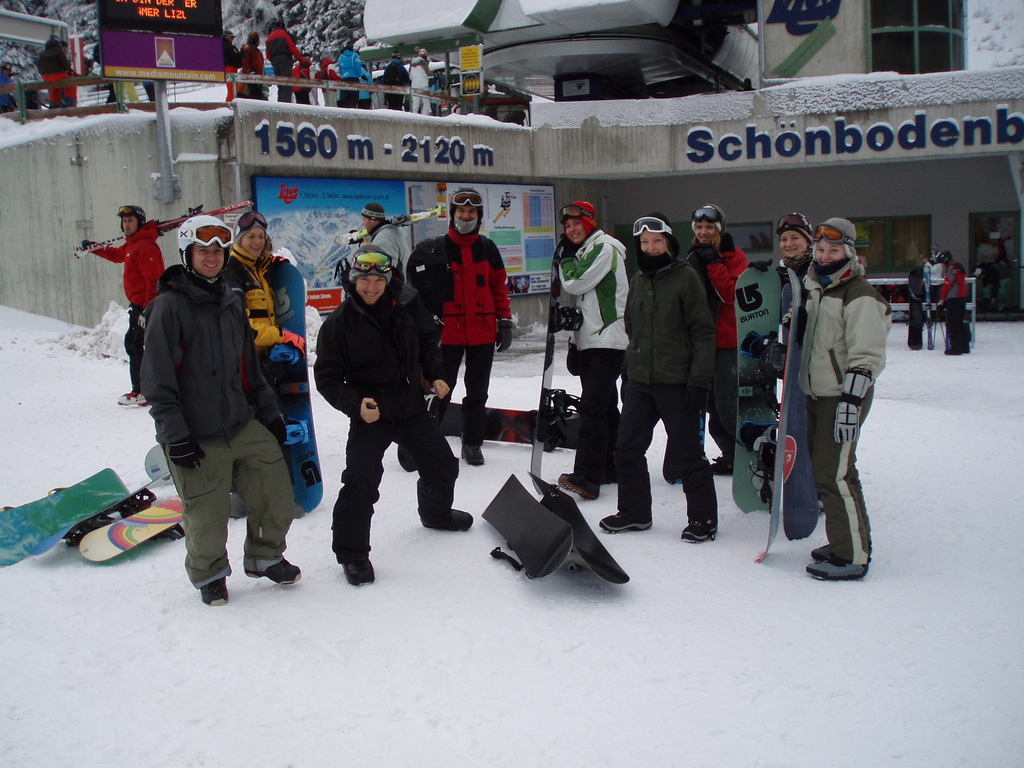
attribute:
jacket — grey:
[138, 273, 284, 447]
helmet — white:
[157, 212, 260, 288]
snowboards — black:
[483, 475, 624, 589]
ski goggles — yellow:
[337, 250, 404, 285]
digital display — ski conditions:
[88, 4, 250, 96]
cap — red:
[549, 196, 601, 232]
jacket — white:
[549, 240, 632, 359]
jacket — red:
[106, 235, 163, 308]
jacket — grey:
[603, 260, 728, 391]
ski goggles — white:
[603, 207, 687, 243]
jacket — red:
[88, 197, 181, 359]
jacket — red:
[88, 203, 175, 339]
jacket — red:
[92, 200, 175, 322]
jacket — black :
[319, 308, 449, 423]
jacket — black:
[129, 288, 275, 432]